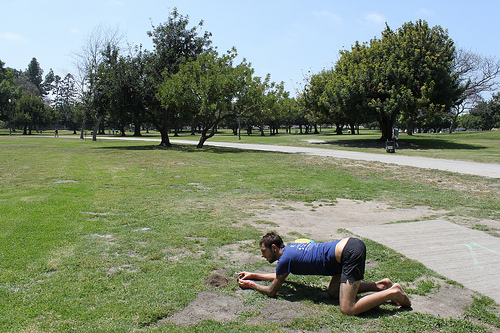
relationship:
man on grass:
[235, 232, 415, 314] [0, 134, 499, 333]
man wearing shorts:
[235, 232, 415, 314] [341, 235, 366, 285]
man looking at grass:
[235, 232, 415, 314] [0, 134, 499, 333]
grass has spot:
[0, 134, 499, 333] [242, 194, 458, 243]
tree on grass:
[157, 46, 293, 149] [0, 134, 499, 333]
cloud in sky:
[363, 10, 385, 27] [1, 1, 498, 118]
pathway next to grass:
[6, 131, 500, 181] [0, 134, 499, 333]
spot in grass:
[242, 194, 458, 243] [0, 134, 499, 333]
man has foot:
[235, 232, 415, 314] [391, 283, 416, 311]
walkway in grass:
[342, 217, 500, 305] [0, 134, 499, 333]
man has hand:
[235, 232, 415, 314] [239, 277, 251, 291]